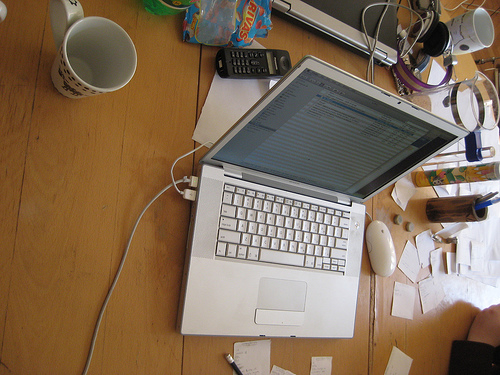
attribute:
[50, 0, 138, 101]
cup — empty